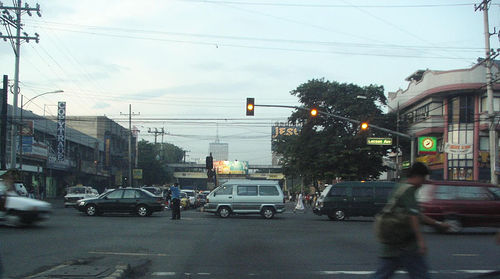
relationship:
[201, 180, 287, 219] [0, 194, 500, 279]
van on road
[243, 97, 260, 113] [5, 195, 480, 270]
light hanging over street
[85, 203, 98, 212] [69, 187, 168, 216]
wheel on vehicle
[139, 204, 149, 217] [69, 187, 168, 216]
wheel on vehicle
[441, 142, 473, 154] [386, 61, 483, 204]
banner hanging off building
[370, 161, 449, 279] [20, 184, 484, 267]
guy crossing street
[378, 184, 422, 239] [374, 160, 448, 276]
shirt on person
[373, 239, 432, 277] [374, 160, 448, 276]
pants on person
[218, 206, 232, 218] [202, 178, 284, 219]
front tire of car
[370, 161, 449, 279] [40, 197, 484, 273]
guy crossing road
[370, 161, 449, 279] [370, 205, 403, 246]
guy has backpack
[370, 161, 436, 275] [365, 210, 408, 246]
guy has backpack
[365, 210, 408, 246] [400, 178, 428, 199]
backpack on shoulder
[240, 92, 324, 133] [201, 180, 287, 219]
traffic signal signaling van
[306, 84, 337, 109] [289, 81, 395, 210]
leaves on tree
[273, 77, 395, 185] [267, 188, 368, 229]
tree on roadside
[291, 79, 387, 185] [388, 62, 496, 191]
tree beside building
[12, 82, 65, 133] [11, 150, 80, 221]
streetlamp on roadside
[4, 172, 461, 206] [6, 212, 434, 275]
traffic on road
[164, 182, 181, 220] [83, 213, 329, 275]
man standing in road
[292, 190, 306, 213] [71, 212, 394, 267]
man walking on road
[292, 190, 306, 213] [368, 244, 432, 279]
man wearing pants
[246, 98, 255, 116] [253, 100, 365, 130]
light on pole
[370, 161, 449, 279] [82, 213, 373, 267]
guy walking across street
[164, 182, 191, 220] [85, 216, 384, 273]
man crossing street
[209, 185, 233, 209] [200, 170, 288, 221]
door of vehicle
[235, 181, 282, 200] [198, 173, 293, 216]
windows of vehicle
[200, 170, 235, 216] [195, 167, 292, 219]
front of vehicle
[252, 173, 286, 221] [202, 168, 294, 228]
rear part of vehicle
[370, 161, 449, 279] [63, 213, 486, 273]
guy crossing street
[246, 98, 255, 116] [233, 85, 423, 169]
light on pole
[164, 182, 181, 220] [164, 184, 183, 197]
man wearing shirt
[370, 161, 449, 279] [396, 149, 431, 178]
guy wearing hat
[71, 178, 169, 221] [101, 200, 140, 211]
car with doors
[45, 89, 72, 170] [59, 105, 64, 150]
sign with letters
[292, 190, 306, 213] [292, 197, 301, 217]
man wearing dress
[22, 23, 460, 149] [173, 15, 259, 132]
sky with clouds